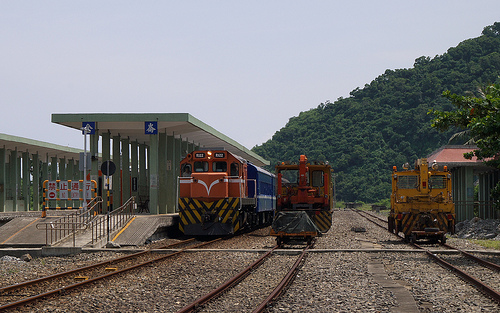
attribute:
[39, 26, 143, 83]
clouds — white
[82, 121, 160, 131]
pictures — white 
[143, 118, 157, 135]
sign — blue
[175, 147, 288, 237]
train — push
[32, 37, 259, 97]
clouds — white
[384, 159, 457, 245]
vehicle — orange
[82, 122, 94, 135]
sign — blue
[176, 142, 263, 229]
train — red 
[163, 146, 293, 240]
train — red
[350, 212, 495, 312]
track — train track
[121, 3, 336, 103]
clouds — white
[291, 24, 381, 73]
sky — blue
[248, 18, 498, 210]
hillside — dark, green, leafy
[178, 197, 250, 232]
bumper — striped 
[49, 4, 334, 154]
sky — blue 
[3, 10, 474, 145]
sky — gray, overcast 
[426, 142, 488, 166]
roof — red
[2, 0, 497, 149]
clouds — white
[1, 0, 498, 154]
sky — blue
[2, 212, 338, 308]
track — steel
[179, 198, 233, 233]
bumper — striped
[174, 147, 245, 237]
front — orange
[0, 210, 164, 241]
ramp — sloped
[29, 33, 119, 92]
cloud — white 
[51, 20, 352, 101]
sky — blue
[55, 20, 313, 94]
sky — blue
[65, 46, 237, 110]
clouds — white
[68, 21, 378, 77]
sky — blue